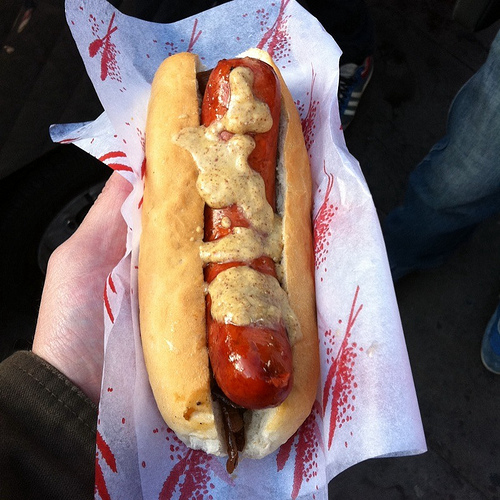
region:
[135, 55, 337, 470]
Hot dog in bun with mustard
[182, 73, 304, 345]
Mustard on a hot dog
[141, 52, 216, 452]
Half of hotdog bun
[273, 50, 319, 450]
Half of hotdog bun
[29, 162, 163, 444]
Hand holding hotdog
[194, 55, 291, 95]
Tip of hotdog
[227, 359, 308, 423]
Tip of tied off hotdog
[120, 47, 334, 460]
Large hotdog with mustard topping and bun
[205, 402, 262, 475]
Caramelized onion under hotdog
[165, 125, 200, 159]
Mustard on the bun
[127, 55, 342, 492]
hot dog on paper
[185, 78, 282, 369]
brown mustard on hot dog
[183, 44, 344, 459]
hot dog is dark red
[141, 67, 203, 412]
bun is light brown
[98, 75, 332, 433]
hot dog on parchment paper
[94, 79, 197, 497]
paper is red and white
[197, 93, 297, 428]
hot dog is in bun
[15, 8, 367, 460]
hot dog in left hand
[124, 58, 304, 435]
bun in red and white paper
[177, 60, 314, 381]
mustard on cooked hot dog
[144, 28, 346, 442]
a tasty hog dog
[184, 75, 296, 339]
delicious melted cheese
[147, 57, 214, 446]
toasted hot dog bread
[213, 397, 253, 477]
salted onion pieces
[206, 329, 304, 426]
a very red hot dog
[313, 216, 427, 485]
a red pattern napkin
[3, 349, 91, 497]
a brown sleeve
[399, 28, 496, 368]
a man in a blue jeans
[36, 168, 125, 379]
the white man hand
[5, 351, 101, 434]
seam of the sleeve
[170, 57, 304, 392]
hot dog is in a bun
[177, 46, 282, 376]
mustard on the hot dog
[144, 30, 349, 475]
hot dog bun is brown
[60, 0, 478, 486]
hot dog on paper wrapper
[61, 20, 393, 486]
red designs on paper wrapper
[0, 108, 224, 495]
man holding the hot dog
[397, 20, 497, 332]
person's blue jeans showing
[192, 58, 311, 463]
hot dog is brown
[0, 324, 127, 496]
man's jacket is brown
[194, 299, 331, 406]
hot dog is greasy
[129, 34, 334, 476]
a hot dog over a paper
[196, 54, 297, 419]
a hot dog is red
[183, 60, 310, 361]
mustard over a hot dog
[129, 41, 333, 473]
bun is long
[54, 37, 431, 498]
paper is white and red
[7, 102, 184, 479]
a hand holding a sandwich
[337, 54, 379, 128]
shoe has white stripes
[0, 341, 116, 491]
a sleeve over the wrist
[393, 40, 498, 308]
leg of a person wearing blue jeans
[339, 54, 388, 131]
a tennis shoe behind a hot dog